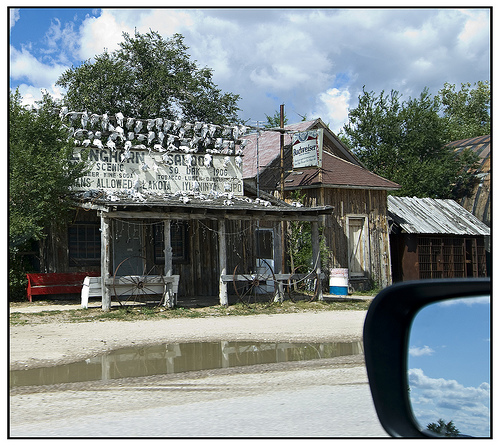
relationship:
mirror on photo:
[362, 275, 487, 437] [12, 7, 491, 435]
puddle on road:
[9, 330, 370, 397] [11, 296, 390, 437]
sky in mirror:
[422, 322, 472, 375] [354, 267, 487, 430]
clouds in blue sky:
[12, 10, 488, 131] [229, 23, 333, 83]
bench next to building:
[81, 275, 185, 307] [29, 111, 336, 304]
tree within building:
[8, 86, 85, 295] [39, 107, 319, 321]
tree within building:
[53, 27, 249, 132] [243, 114, 390, 305]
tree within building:
[258, 101, 294, 133] [380, 184, 492, 281]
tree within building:
[343, 90, 476, 195] [39, 107, 319, 321]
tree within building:
[434, 76, 491, 139] [243, 114, 390, 305]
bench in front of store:
[24, 270, 106, 301] [27, 108, 334, 307]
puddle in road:
[9, 330, 370, 397] [11, 296, 390, 437]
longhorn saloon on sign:
[69, 146, 216, 166] [57, 146, 245, 200]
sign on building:
[57, 146, 245, 200] [25, 73, 481, 338]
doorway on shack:
[348, 216, 366, 272] [272, 148, 399, 293]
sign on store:
[57, 142, 245, 200] [52, 99, 394, 308]